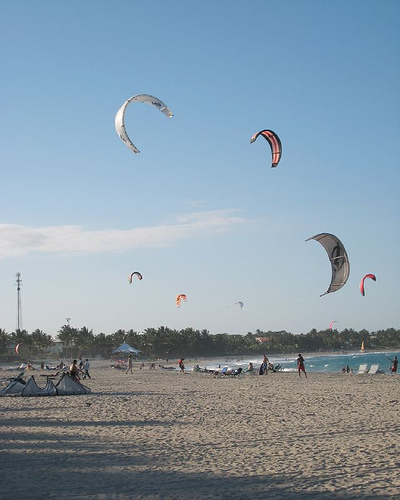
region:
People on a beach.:
[11, 342, 399, 419]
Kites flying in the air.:
[95, 77, 381, 325]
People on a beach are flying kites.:
[12, 81, 397, 482]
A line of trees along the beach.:
[3, 321, 399, 366]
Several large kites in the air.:
[95, 80, 393, 334]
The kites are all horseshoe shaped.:
[84, 84, 393, 328]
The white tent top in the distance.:
[112, 341, 135, 352]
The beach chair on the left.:
[356, 363, 366, 373]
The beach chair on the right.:
[368, 361, 377, 377]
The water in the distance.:
[237, 351, 399, 376]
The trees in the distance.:
[1, 323, 396, 353]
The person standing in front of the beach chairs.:
[291, 351, 313, 377]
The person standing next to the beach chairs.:
[388, 351, 399, 378]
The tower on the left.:
[12, 266, 25, 332]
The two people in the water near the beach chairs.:
[340, 363, 350, 371]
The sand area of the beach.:
[1, 358, 398, 499]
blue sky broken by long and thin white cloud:
[4, 12, 396, 333]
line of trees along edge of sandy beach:
[3, 322, 395, 456]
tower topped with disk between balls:
[12, 268, 24, 333]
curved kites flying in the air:
[125, 228, 377, 315]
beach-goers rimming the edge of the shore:
[161, 343, 397, 386]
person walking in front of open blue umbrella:
[107, 336, 141, 374]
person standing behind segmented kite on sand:
[3, 355, 95, 403]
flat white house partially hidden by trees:
[28, 328, 81, 358]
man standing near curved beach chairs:
[351, 351, 397, 377]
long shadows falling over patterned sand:
[7, 368, 393, 490]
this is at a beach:
[29, 72, 337, 413]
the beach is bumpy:
[118, 380, 295, 462]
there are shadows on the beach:
[53, 432, 149, 499]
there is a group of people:
[115, 320, 275, 398]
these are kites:
[83, 61, 327, 282]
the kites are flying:
[91, 93, 375, 323]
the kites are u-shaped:
[98, 86, 349, 324]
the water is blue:
[275, 343, 389, 379]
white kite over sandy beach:
[107, 88, 180, 158]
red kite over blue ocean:
[353, 271, 379, 300]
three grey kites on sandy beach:
[0, 374, 95, 396]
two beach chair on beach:
[349, 362, 381, 377]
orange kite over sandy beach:
[171, 290, 192, 310]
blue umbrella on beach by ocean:
[110, 341, 140, 373]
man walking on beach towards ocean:
[122, 353, 135, 375]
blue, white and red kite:
[249, 128, 283, 169]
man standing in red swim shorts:
[295, 352, 309, 377]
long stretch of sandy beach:
[0, 348, 399, 498]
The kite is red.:
[352, 262, 375, 297]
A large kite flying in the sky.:
[306, 227, 355, 297]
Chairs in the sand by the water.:
[358, 359, 382, 378]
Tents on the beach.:
[4, 369, 86, 401]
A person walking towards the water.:
[126, 352, 135, 373]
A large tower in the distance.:
[10, 268, 28, 333]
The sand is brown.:
[4, 399, 398, 499]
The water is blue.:
[245, 352, 399, 370]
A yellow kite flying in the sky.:
[168, 288, 192, 312]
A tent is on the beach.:
[111, 339, 139, 354]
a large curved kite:
[114, 93, 170, 152]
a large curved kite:
[128, 269, 144, 282]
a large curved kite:
[175, 291, 187, 307]